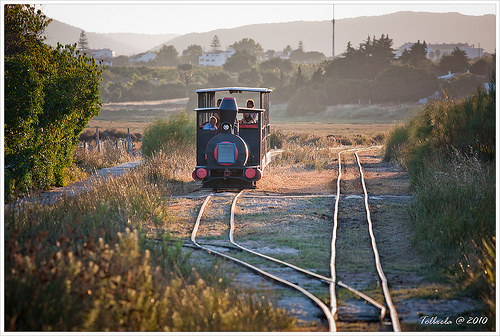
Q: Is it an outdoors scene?
A: Yes, it is outdoors.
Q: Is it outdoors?
A: Yes, it is outdoors.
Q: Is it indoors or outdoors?
A: It is outdoors.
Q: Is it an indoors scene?
A: No, it is outdoors.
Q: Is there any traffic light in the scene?
A: No, there are no traffic lights.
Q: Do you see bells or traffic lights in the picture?
A: No, there are no traffic lights or bells.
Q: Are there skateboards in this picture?
A: No, there are no skateboards.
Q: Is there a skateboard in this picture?
A: No, there are no skateboards.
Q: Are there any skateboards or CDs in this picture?
A: No, there are no skateboards or cds.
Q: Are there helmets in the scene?
A: No, there are no helmets.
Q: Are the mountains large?
A: Yes, the mountains are large.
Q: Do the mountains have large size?
A: Yes, the mountains are large.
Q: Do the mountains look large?
A: Yes, the mountains are large.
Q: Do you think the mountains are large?
A: Yes, the mountains are large.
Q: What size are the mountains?
A: The mountains are large.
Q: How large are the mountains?
A: The mountains are large.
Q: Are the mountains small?
A: No, the mountains are large.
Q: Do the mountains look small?
A: No, the mountains are large.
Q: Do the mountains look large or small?
A: The mountains are large.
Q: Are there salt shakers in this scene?
A: No, there are no salt shakers.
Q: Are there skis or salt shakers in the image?
A: No, there are no salt shakers or skis.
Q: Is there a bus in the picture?
A: No, there are no buses.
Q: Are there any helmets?
A: No, there are no helmets.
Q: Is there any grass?
A: Yes, there is grass.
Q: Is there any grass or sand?
A: Yes, there is grass.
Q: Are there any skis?
A: No, there are no skis.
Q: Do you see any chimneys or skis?
A: No, there are no skis or chimneys.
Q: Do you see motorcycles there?
A: No, there are no motorcycles.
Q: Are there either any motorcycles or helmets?
A: No, there are no motorcycles or helmets.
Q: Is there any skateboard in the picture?
A: No, there are no skateboards.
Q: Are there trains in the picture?
A: Yes, there is a train.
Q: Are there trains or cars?
A: Yes, there is a train.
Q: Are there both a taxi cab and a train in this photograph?
A: No, there is a train but no taxis.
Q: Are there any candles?
A: No, there are no candles.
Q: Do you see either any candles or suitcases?
A: No, there are no candles or suitcases.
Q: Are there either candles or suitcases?
A: No, there are no candles or suitcases.